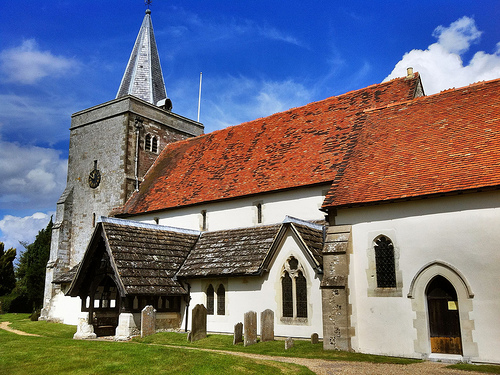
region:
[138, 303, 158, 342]
Tombstone in the cemetery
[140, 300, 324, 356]
Group of seven tombstones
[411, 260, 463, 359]
Wooden door way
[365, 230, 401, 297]
Window on the building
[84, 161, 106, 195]
Circular clock face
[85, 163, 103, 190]
Clock on the side of the building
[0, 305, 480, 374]
Gravel pathway through green grass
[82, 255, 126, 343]
Entrance to the church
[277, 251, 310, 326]
Set of stained glass windows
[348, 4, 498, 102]
Fluffy white clouds in the blue sky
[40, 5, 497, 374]
an old country church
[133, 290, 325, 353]
a small church cemetary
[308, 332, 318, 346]
a small tombstone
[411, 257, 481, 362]
an arched entryway to the church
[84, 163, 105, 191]
a clock on a tower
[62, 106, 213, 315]
a grey stone tower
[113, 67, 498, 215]
a red roof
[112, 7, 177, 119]
a church building's steeple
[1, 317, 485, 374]
a path going to the building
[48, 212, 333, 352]
a dark grey roofed building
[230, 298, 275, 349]
three small concrete tombstones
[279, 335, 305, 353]
one tiny grey headstone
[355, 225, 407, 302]
oval window opening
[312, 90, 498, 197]
red roof on building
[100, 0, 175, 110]
triangular pointed grey steeple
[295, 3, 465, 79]
bright blue sky with white clouds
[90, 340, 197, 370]
green grass with sidewalk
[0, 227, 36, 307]
trees in the distance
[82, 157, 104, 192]
ornate decoration on the side of church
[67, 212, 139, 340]
small triangular opening on side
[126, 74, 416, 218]
red and black shingle slanted roof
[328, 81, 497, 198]
red and black shingle slanted roof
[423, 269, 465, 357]
arched open doorway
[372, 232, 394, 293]
narrow arched window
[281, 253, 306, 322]
narrow arched window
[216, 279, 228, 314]
narrow arched window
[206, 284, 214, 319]
narrow arched window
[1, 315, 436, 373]
dirt and gravel path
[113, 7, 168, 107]
tall gray shingle steeple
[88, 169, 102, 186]
black and gold circular clock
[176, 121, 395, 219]
Red roof shingles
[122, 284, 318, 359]
Basic grey headstones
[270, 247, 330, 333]
Tall ornate window with three panes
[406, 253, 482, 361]
Arched black and yellow door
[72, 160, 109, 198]
Large dark clock set on church wall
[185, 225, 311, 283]
Black and grey roof shingles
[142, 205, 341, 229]
Numerous small windows across wall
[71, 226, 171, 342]
Tall arched doorway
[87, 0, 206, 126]
Light grey church steeple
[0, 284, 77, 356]
Dirt path through green grass